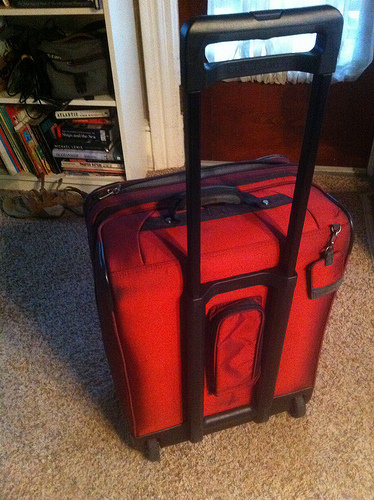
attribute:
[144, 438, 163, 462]
wheel — black , small 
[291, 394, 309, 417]
wheel — small , black 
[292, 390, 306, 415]
wheel — black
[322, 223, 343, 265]
zipper — black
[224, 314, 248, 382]
stain — curvy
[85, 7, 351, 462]
travel case — black, red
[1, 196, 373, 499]
carpet — plush, brown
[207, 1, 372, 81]
curtain — gauzy, light blue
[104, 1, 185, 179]
door frame — white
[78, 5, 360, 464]
luggage — red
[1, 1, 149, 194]
bookshelf — white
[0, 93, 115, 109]
shelf — black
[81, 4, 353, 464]
suitcase — red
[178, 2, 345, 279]
handle — black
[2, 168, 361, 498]
carpet — tan